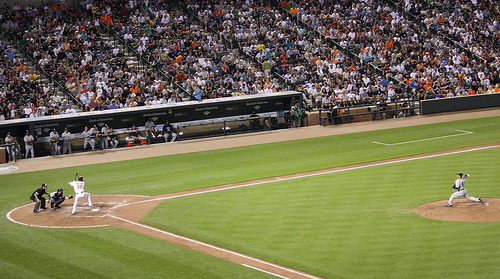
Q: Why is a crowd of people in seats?
A: To watch a game.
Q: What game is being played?
A: Baseball.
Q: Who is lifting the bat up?
A: The batter.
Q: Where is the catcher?
A: Behind the batter.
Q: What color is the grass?
A: Green.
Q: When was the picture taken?
A: At daytime.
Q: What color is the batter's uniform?
A: White.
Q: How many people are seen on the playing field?
A: Four.